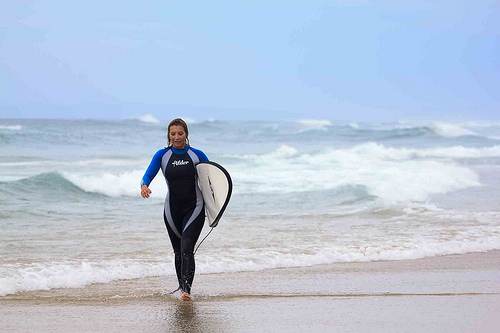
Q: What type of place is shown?
A: It is an ocean.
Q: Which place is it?
A: It is an ocean.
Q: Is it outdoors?
A: Yes, it is outdoors.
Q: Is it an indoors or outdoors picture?
A: It is outdoors.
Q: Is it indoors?
A: No, it is outdoors.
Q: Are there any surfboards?
A: Yes, there is a surfboard.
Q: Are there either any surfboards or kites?
A: Yes, there is a surfboard.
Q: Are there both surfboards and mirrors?
A: No, there is a surfboard but no mirrors.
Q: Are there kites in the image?
A: No, there are no kites.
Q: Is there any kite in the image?
A: No, there are no kites.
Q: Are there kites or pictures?
A: No, there are no kites or pictures.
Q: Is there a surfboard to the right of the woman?
A: Yes, there is a surfboard to the right of the woman.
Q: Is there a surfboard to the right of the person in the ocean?
A: Yes, there is a surfboard to the right of the woman.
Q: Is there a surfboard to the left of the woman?
A: No, the surfboard is to the right of the woman.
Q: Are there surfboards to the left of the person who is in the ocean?
A: No, the surfboard is to the right of the woman.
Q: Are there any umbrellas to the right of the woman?
A: No, there is a surfboard to the right of the woman.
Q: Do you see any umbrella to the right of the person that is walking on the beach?
A: No, there is a surfboard to the right of the woman.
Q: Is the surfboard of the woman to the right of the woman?
A: Yes, the surf board is to the right of the woman.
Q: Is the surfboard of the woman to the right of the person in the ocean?
A: Yes, the surf board is to the right of the woman.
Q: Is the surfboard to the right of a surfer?
A: No, the surfboard is to the right of the woman.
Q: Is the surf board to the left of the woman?
A: No, the surf board is to the right of the woman.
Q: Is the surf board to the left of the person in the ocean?
A: No, the surf board is to the right of the woman.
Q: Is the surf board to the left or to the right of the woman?
A: The surf board is to the right of the woman.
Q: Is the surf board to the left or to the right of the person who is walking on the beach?
A: The surf board is to the right of the woman.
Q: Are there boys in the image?
A: No, there are no boys.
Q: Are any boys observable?
A: No, there are no boys.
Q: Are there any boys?
A: No, there are no boys.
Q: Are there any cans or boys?
A: No, there are no boys or cans.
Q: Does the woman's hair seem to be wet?
A: Yes, the hair is wet.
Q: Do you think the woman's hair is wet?
A: Yes, the hair is wet.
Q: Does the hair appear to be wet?
A: Yes, the hair is wet.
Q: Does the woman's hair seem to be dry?
A: No, the hair is wet.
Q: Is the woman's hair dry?
A: No, the hair is wet.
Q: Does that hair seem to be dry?
A: No, the hair is wet.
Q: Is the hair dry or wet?
A: The hair is wet.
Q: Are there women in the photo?
A: Yes, there is a woman.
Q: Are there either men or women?
A: Yes, there is a woman.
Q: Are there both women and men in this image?
A: No, there is a woman but no men.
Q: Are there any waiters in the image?
A: No, there are no waiters.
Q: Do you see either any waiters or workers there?
A: No, there are no waiters or workers.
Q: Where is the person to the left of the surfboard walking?
A: The woman is walking on the beach.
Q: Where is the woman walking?
A: The woman is walking on the beach.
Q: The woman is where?
A: The woman is in the ocean.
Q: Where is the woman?
A: The woman is in the ocean.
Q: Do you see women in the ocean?
A: Yes, there is a woman in the ocean.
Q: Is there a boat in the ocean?
A: No, there is a woman in the ocean.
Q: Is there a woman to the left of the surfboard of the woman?
A: Yes, there is a woman to the left of the surfboard.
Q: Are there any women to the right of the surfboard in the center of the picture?
A: No, the woman is to the left of the surfboard.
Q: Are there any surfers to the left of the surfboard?
A: No, there is a woman to the left of the surfboard.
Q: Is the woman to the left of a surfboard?
A: Yes, the woman is to the left of a surfboard.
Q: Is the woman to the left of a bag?
A: No, the woman is to the left of a surfboard.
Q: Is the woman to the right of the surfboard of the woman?
A: No, the woman is to the left of the surf board.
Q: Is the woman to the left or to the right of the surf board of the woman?
A: The woman is to the left of the surf board.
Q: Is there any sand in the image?
A: Yes, there is sand.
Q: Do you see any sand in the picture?
A: Yes, there is sand.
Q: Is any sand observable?
A: Yes, there is sand.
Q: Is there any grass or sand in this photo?
A: Yes, there is sand.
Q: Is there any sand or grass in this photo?
A: Yes, there is sand.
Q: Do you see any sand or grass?
A: Yes, there is sand.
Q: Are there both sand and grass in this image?
A: No, there is sand but no grass.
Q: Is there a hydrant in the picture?
A: No, there are no fire hydrants.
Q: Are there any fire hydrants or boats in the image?
A: No, there are no fire hydrants or boats.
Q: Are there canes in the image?
A: No, there are no canes.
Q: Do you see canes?
A: No, there are no canes.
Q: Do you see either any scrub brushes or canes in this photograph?
A: No, there are no canes or scrub brushes.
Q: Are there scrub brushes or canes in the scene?
A: No, there are no canes or scrub brushes.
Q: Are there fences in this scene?
A: No, there are no fences.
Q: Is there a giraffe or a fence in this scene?
A: No, there are no fences or giraffes.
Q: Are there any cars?
A: No, there are no cars.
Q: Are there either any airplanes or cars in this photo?
A: No, there are no cars or airplanes.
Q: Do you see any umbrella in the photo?
A: No, there are no umbrellas.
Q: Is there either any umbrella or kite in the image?
A: No, there are no umbrellas or kites.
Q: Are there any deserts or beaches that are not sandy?
A: No, there is a beach but it is sandy.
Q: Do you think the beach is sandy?
A: Yes, the beach is sandy.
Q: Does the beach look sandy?
A: Yes, the beach is sandy.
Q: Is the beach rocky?
A: No, the beach is sandy.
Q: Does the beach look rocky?
A: No, the beach is sandy.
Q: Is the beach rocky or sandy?
A: The beach is sandy.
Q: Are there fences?
A: No, there are no fences.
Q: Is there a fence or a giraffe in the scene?
A: No, there are no fences or giraffes.